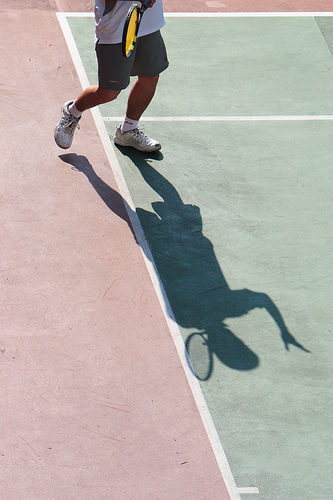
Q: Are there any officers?
A: No, there are no officers.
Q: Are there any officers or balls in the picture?
A: No, there are no officers or balls.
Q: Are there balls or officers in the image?
A: No, there are no officers or balls.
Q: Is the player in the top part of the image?
A: Yes, the player is in the top of the image.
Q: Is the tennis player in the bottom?
A: No, the player is in the top of the image.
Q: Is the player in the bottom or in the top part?
A: The player is in the top of the image.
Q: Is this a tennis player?
A: Yes, this is a tennis player.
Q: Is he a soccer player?
A: No, this is a tennis player.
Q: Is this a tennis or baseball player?
A: This is a tennis player.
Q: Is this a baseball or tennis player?
A: This is a tennis player.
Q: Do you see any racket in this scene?
A: Yes, there is a racket.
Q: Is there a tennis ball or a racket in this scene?
A: Yes, there is a racket.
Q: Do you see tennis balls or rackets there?
A: Yes, there is a racket.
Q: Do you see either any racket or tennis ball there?
A: Yes, there is a racket.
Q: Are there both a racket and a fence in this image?
A: No, there is a racket but no fences.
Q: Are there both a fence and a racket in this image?
A: No, there is a racket but no fences.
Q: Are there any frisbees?
A: No, there are no frisbees.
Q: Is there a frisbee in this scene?
A: No, there are no frisbees.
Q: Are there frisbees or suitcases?
A: No, there are no frisbees or suitcases.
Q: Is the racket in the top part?
A: Yes, the racket is in the top of the image.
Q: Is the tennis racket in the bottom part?
A: No, the tennis racket is in the top of the image.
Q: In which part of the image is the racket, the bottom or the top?
A: The racket is in the top of the image.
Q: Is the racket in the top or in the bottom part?
A: The racket is in the top of the image.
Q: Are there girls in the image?
A: No, there are no girls.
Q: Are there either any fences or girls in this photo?
A: No, there are no girls or fences.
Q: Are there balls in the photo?
A: No, there are no balls.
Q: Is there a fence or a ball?
A: No, there are no balls or fences.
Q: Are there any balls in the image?
A: No, there are no balls.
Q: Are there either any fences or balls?
A: No, there are no balls or fences.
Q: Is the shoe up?
A: Yes, the shoe is up.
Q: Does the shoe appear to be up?
A: Yes, the shoe is up.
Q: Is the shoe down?
A: No, the shoe is up.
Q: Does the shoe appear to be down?
A: No, the shoe is up.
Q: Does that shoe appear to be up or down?
A: The shoe is up.